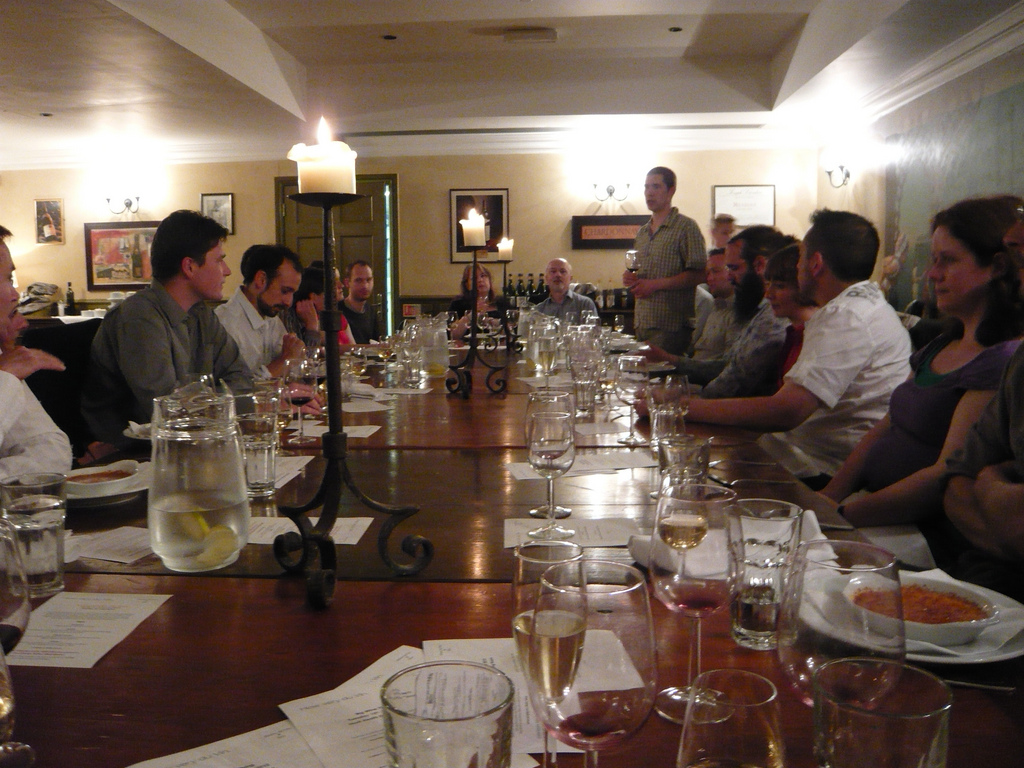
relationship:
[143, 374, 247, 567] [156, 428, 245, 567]
pitcher of water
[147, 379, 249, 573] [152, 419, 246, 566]
pitcher with water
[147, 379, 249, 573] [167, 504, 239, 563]
pitcher with lemons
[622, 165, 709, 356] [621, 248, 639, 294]
man holding beverage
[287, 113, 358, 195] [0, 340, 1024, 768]
candle burning on dinner table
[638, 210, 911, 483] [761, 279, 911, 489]
man wearing shirt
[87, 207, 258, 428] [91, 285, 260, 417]
man wearing shirt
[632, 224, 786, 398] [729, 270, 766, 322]
man sporting a beard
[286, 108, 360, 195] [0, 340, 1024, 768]
candle on dinner table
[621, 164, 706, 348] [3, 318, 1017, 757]
man standing at dinner table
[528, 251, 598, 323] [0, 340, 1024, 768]
gentleman at head of dinner table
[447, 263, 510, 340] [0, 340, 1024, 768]
woman sitting at head of dinner table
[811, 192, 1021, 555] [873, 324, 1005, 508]
woman wearing a top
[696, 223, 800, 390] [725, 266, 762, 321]
man with beard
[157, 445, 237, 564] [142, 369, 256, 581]
water in pitcher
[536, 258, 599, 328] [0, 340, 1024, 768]
gentleman sitting at dinner table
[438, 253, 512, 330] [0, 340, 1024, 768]
woman sitting at dinner table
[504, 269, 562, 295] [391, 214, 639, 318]
wine bottles against wall